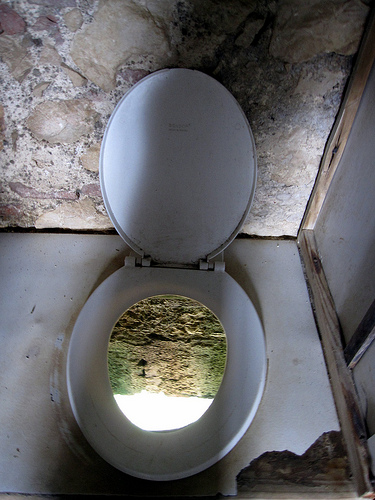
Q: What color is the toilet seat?
A: White.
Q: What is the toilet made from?
A: Plastic.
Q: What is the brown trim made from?
A: Wood.